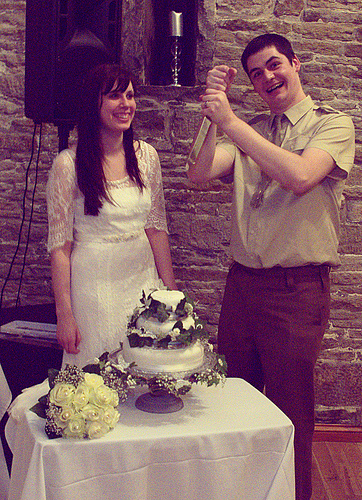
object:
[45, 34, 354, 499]
people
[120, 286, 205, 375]
cake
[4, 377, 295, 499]
table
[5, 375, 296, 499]
table cloth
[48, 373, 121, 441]
rose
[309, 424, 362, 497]
floor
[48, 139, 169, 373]
dress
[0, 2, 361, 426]
wall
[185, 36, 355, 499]
man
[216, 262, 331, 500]
pants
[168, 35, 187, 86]
candle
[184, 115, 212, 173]
knife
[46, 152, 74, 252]
sleeve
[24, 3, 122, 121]
speaker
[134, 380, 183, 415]
pedestal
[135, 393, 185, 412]
base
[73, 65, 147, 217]
hair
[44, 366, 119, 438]
bouquet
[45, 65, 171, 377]
bride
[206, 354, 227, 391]
leaves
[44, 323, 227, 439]
flowers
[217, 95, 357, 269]
shirt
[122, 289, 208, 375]
tiers